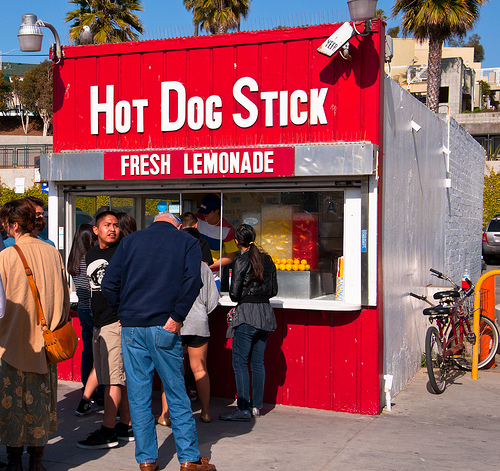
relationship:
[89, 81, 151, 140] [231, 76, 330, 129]
hot dog stick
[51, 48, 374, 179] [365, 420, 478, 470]
restaurant on road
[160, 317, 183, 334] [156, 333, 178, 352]
hands in pocket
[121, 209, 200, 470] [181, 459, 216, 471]
person wearing shoe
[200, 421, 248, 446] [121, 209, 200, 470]
shadow of person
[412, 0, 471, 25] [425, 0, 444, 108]
green palm tree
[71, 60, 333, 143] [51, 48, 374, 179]
sign on building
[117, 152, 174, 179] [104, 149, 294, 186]
fresh lemonade sign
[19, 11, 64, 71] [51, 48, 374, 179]
light on building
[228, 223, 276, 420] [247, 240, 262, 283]
woman with ponytail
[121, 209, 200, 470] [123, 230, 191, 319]
man in jacket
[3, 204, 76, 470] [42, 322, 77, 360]
woman with bag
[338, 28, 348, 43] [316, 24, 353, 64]
white security camera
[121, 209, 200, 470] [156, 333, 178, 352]
man in pocket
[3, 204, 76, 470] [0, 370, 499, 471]
woman on road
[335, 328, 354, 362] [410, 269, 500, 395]
red parked bike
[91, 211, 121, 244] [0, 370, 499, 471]
man on road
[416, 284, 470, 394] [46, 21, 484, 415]
bike near restaurant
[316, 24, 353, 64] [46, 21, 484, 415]
camera on restaurant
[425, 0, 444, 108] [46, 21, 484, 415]
tree behind restaurant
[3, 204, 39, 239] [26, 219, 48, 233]
hair in bun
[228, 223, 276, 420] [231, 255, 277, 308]
girl wearing jacket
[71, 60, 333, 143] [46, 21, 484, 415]
sign on restaurant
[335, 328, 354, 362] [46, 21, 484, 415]
red on restaurant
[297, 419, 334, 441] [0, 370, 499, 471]
gray on road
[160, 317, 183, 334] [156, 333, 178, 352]
hand in pocket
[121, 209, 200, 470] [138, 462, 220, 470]
man wearing shoes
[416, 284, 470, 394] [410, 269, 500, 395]
bike parked on bike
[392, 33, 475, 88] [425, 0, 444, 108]
house behind tree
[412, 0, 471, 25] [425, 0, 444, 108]
green cultivated tree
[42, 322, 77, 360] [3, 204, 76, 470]
bag on woman